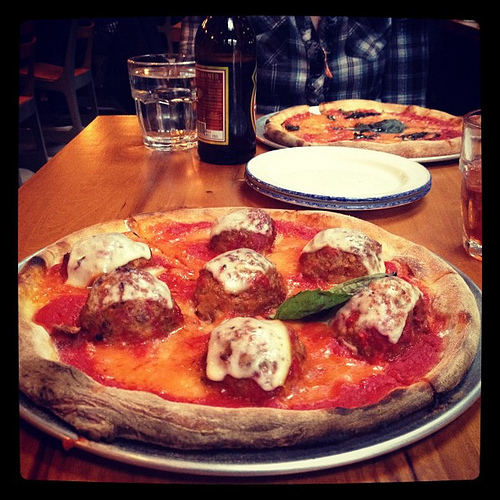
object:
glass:
[114, 35, 209, 160]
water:
[128, 82, 201, 152]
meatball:
[198, 308, 309, 407]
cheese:
[222, 319, 278, 370]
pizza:
[10, 190, 489, 456]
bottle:
[190, 0, 268, 172]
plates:
[240, 141, 437, 205]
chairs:
[0, 0, 114, 143]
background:
[10, 0, 483, 121]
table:
[19, 111, 485, 486]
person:
[219, 14, 483, 123]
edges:
[271, 186, 329, 198]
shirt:
[254, 11, 434, 114]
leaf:
[269, 270, 391, 327]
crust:
[32, 384, 399, 453]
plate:
[249, 86, 481, 165]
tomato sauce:
[336, 329, 453, 409]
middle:
[40, 155, 482, 191]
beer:
[195, 52, 259, 167]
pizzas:
[251, 63, 484, 161]